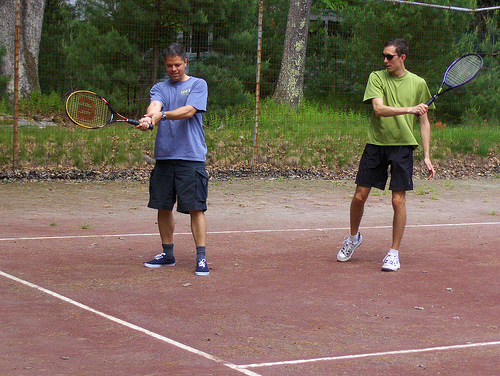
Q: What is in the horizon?
A: A building.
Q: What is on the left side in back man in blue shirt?
A: Tree.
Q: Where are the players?
A: Tennis court.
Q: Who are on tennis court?
A: 2 men.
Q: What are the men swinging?
A: Rackets.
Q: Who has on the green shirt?
A: Man on right.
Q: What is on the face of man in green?
A: Shades.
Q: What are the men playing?
A: Tennis.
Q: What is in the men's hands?
A: Rackets.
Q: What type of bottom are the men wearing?
A: Shorts.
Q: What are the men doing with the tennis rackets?
A: Swinging them.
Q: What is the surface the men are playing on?
A: Tennis court.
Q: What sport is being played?
A: Tennis.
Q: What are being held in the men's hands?
A: Rackets.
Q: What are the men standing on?
A: A tennis court.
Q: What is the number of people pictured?
A: Two.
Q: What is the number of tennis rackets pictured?
A: Two.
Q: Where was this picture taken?
A: At a tennis court.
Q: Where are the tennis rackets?
A: In the men's hands.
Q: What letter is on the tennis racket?
A: W.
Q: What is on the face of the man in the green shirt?
A: Sunglasses.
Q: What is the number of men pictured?
A: Two.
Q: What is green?
A: A man's shirt.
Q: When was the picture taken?
A: During the day.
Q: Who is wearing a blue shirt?
A: Man on left.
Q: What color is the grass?
A: Green.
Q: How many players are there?
A: Two.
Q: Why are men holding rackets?
A: To play tennis.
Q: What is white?
A: Lines on the court.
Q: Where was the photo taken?
A: At a tennis court.